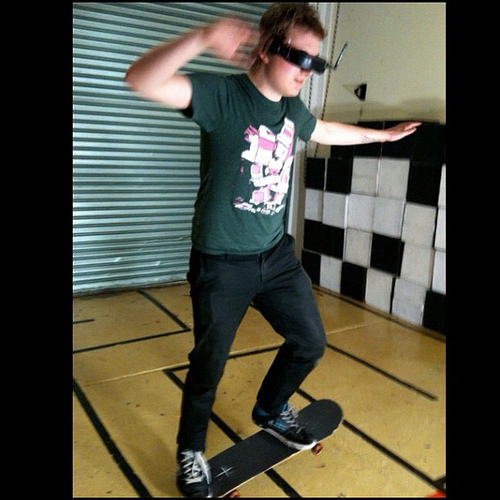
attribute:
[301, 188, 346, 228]
square — white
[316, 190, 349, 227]
square — white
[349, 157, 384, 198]
square — white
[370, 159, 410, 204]
square — white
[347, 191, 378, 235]
square — white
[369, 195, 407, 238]
square — white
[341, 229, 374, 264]
square — white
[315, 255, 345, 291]
square — white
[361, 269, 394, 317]
square — white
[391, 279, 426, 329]
square — white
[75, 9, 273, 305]
door — silver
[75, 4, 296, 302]
door — silver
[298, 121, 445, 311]
tiles — black, white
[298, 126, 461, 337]
tiles — white, black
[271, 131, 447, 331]
tiles — black, white